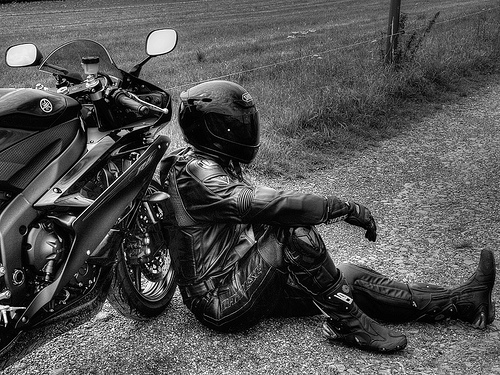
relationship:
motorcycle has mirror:
[1, 35, 180, 340] [142, 29, 191, 67]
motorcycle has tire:
[1, 35, 180, 340] [114, 180, 174, 322]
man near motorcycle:
[136, 102, 440, 375] [1, 35, 180, 340]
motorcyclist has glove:
[136, 102, 440, 375] [333, 199, 384, 241]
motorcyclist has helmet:
[136, 102, 440, 375] [162, 81, 269, 151]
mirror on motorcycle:
[142, 29, 191, 67] [1, 35, 180, 340]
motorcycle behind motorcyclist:
[1, 35, 180, 340] [136, 102, 440, 375]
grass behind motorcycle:
[273, 29, 382, 133] [1, 35, 180, 340]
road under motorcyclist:
[373, 94, 494, 240] [136, 102, 440, 375]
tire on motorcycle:
[114, 180, 174, 322] [1, 35, 180, 340]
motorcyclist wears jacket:
[136, 102, 440, 375] [156, 154, 300, 317]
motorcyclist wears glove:
[136, 102, 440, 375] [333, 199, 384, 241]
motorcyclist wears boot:
[136, 102, 440, 375] [377, 254, 496, 333]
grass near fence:
[273, 29, 382, 133] [246, 1, 427, 71]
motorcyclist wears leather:
[136, 102, 440, 375] [175, 143, 343, 303]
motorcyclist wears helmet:
[136, 102, 440, 375] [162, 81, 269, 151]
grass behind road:
[273, 29, 382, 133] [373, 94, 494, 240]